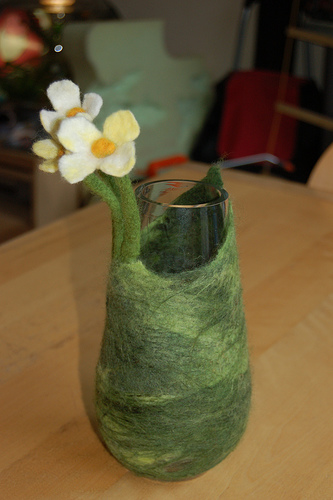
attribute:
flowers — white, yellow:
[54, 111, 147, 183]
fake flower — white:
[34, 77, 141, 182]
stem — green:
[86, 174, 139, 268]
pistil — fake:
[92, 136, 117, 159]